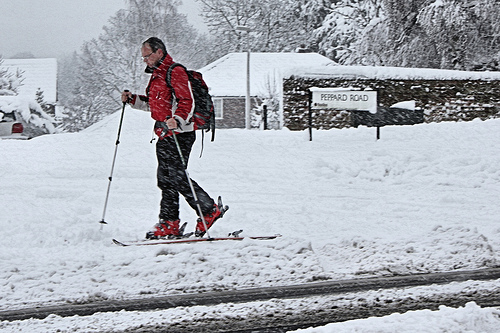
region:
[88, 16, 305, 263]
The man is not wearing a hat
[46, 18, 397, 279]
It looks very cold outside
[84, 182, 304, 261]
The man is wearing ski's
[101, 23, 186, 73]
The man has dark hair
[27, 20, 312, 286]
It is snowing very hard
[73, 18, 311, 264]
The wind is blowing the snow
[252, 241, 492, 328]
There are tire tracks in the snow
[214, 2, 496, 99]
The trees are snow covered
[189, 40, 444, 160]
The roof is covered with snow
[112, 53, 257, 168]
The man is wearing a red jacket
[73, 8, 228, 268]
a man wearing skis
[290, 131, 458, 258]
snow covering the ground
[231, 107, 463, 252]
the ground covered with snow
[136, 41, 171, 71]
a man wearing glasses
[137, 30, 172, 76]
a man with short hair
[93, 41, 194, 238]
a man holding ski poles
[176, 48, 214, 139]
a man with a back pack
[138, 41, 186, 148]
a man wearing a red jacket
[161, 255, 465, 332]
vehicle tracks in the snow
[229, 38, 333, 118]
a building with snow on the roof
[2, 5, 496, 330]
snow falling on a cross country skier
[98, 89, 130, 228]
aluminum ski pole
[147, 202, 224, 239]
red ski boots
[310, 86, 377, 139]
shephard road sign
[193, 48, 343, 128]
house with a snow covered roof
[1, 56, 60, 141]
house with a snowy rooftop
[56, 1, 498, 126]
trees covered in snow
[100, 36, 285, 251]
cross country skier wearing red and white parka, dark pants, and a backpack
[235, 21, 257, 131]
exterior light on tall pole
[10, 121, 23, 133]
small red car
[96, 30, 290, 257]
a man walking on snow skies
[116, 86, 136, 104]
the handle of the pole in his hand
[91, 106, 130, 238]
the black ski pole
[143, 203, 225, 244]
the red boots on the skiier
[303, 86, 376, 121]
a white sign in the snow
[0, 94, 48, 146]
a car covered in snow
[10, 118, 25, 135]
the red tailight of the car covered in snow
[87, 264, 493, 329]
The tracks in the snow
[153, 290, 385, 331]
The black cement road underneath the snow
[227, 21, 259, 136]
a white street light covered in snow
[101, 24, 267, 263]
man in skiis in snow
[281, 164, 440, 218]
white snow on ground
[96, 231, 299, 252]
skiis man is using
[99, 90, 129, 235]
ski pole in man's right hand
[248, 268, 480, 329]
tracks in the road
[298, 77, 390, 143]
sign on two poles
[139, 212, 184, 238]
right snow boot on man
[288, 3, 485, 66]
white snow covered trees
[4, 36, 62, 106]
building in the background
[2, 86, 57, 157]
car parked with snow on top